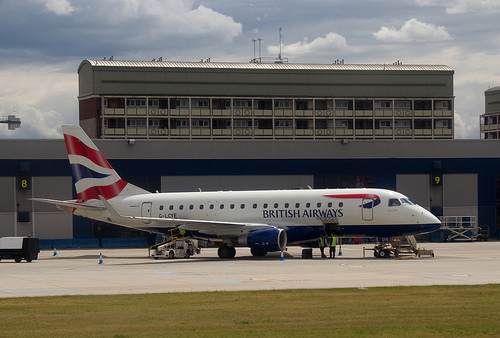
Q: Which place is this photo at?
A: It is at the airport.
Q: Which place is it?
A: It is an airport.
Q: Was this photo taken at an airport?
A: Yes, it was taken in an airport.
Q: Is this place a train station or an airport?
A: It is an airport.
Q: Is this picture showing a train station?
A: No, the picture is showing an airport.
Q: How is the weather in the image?
A: It is cloudy.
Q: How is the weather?
A: It is cloudy.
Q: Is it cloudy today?
A: Yes, it is cloudy.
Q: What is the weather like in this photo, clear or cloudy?
A: It is cloudy.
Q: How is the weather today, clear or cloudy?
A: It is cloudy.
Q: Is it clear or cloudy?
A: It is cloudy.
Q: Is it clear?
A: No, it is cloudy.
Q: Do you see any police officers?
A: No, there are no police officers.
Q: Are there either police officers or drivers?
A: No, there are no police officers or drivers.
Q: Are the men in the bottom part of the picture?
A: Yes, the men are in the bottom of the image.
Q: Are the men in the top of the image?
A: No, the men are in the bottom of the image.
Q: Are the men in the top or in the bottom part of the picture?
A: The men are in the bottom of the image.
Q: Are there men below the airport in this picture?
A: Yes, there are men below the airport.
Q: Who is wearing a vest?
A: The men are wearing a vest.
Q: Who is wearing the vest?
A: The men are wearing a vest.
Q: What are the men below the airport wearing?
A: The men are wearing a vest.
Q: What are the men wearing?
A: The men are wearing a vest.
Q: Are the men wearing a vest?
A: Yes, the men are wearing a vest.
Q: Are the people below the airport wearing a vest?
A: Yes, the men are wearing a vest.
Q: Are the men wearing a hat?
A: No, the men are wearing a vest.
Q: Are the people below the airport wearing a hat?
A: No, the men are wearing a vest.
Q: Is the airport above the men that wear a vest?
A: Yes, the airport is above the men.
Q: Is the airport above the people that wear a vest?
A: Yes, the airport is above the men.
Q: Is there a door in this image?
A: Yes, there is a door.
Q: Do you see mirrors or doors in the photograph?
A: Yes, there is a door.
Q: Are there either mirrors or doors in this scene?
A: Yes, there is a door.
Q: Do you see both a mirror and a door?
A: No, there is a door but no mirrors.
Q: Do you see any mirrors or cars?
A: No, there are no cars or mirrors.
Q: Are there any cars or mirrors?
A: No, there are no cars or mirrors.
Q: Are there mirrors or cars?
A: No, there are no cars or mirrors.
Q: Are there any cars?
A: No, there are no cars.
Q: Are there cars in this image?
A: No, there are no cars.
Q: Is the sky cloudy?
A: Yes, the sky is cloudy.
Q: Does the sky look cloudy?
A: Yes, the sky is cloudy.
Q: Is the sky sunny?
A: No, the sky is cloudy.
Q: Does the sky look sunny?
A: No, the sky is cloudy.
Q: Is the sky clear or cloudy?
A: The sky is cloudy.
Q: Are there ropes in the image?
A: No, there are no ropes.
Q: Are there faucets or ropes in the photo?
A: No, there are no ropes or faucets.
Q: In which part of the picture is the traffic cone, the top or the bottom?
A: The traffic cone is in the bottom of the image.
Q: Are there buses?
A: No, there are no buses.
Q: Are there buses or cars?
A: No, there are no buses or cars.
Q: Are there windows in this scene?
A: Yes, there are windows.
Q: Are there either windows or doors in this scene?
A: Yes, there are windows.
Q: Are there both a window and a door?
A: Yes, there are both a window and a door.